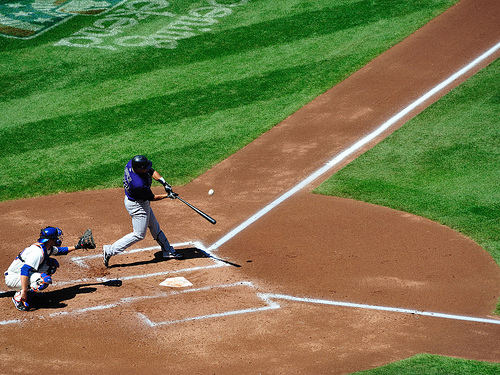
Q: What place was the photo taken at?
A: It was taken at the field.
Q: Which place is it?
A: It is a field.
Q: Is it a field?
A: Yes, it is a field.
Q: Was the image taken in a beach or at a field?
A: It was taken at a field.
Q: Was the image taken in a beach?
A: No, the picture was taken in a field.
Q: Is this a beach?
A: No, it is a field.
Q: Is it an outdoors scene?
A: Yes, it is outdoors.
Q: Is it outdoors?
A: Yes, it is outdoors.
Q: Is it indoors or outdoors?
A: It is outdoors.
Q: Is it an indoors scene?
A: No, it is outdoors.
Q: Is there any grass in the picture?
A: Yes, there is grass.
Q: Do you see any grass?
A: Yes, there is grass.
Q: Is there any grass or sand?
A: Yes, there is grass.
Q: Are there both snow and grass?
A: No, there is grass but no snow.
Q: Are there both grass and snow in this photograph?
A: No, there is grass but no snow.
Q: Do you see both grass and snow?
A: No, there is grass but no snow.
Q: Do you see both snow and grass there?
A: No, there is grass but no snow.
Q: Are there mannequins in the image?
A: No, there are no mannequins.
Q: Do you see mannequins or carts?
A: No, there are no mannequins or carts.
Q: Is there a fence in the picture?
A: No, there are no fences.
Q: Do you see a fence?
A: No, there are no fences.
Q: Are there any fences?
A: No, there are no fences.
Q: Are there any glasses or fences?
A: No, there are no fences or glasses.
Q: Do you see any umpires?
A: No, there are no umpires.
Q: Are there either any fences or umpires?
A: No, there are no umpires or fences.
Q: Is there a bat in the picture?
A: Yes, there is a bat.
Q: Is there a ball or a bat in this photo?
A: Yes, there is a bat.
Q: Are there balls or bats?
A: Yes, there is a bat.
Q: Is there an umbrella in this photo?
A: No, there are no umbrellas.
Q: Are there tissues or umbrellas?
A: No, there are no umbrellas or tissues.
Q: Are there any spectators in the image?
A: No, there are no spectators.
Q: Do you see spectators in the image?
A: No, there are no spectators.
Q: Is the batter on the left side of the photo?
A: Yes, the batter is on the left of the image.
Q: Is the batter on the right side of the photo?
A: No, the batter is on the left of the image.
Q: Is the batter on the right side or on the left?
A: The batter is on the left of the image.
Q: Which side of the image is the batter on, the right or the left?
A: The batter is on the left of the image.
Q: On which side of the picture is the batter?
A: The batter is on the left of the image.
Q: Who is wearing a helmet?
A: The batter is wearing a helmet.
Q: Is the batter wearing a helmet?
A: Yes, the batter is wearing a helmet.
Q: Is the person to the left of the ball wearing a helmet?
A: Yes, the batter is wearing a helmet.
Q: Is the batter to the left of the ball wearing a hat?
A: No, the batter is wearing a helmet.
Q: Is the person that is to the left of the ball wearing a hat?
A: No, the batter is wearing a helmet.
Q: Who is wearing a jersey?
A: The batter is wearing a jersey.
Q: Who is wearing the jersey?
A: The batter is wearing a jersey.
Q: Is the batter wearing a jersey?
A: Yes, the batter is wearing a jersey.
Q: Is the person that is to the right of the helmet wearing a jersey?
A: Yes, the batter is wearing a jersey.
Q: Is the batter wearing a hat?
A: No, the batter is wearing a jersey.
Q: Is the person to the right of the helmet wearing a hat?
A: No, the batter is wearing a jersey.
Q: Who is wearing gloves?
A: The batter is wearing gloves.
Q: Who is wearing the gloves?
A: The batter is wearing gloves.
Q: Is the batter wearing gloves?
A: Yes, the batter is wearing gloves.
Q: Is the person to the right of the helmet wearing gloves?
A: Yes, the batter is wearing gloves.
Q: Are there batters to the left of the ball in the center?
A: Yes, there is a batter to the left of the ball.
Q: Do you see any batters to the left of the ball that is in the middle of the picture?
A: Yes, there is a batter to the left of the ball.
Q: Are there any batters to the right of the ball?
A: No, the batter is to the left of the ball.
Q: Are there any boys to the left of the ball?
A: No, there is a batter to the left of the ball.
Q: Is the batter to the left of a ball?
A: Yes, the batter is to the left of a ball.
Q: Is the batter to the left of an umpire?
A: No, the batter is to the left of a ball.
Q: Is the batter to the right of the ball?
A: No, the batter is to the left of the ball.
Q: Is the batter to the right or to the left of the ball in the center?
A: The batter is to the left of the ball.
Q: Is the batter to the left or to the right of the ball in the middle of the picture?
A: The batter is to the left of the ball.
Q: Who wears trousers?
A: The batter wears trousers.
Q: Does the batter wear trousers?
A: Yes, the batter wears trousers.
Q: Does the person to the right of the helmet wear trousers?
A: Yes, the batter wears trousers.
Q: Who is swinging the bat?
A: The batter is swinging the bat.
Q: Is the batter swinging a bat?
A: Yes, the batter is swinging a bat.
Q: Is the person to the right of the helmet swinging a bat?
A: Yes, the batter is swinging a bat.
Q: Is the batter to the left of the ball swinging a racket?
A: No, the batter is swinging a bat.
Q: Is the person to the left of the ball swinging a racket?
A: No, the batter is swinging a bat.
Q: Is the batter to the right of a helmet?
A: Yes, the batter is to the right of a helmet.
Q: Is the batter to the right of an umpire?
A: No, the batter is to the right of a helmet.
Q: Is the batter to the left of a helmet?
A: No, the batter is to the right of a helmet.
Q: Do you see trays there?
A: No, there are no trays.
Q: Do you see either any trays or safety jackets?
A: No, there are no trays or safety jackets.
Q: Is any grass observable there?
A: Yes, there is grass.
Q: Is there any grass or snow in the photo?
A: Yes, there is grass.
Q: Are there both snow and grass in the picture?
A: No, there is grass but no snow.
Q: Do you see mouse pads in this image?
A: No, there are no mouse pads.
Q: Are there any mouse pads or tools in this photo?
A: No, there are no mouse pads or tools.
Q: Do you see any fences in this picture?
A: No, there are no fences.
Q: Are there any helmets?
A: Yes, there is a helmet.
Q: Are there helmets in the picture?
A: Yes, there is a helmet.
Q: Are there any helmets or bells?
A: Yes, there is a helmet.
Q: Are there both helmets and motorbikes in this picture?
A: No, there is a helmet but no motorcycles.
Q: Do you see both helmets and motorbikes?
A: No, there is a helmet but no motorcycles.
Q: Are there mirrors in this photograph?
A: No, there are no mirrors.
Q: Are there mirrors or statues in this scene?
A: No, there are no mirrors or statues.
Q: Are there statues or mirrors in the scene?
A: No, there are no mirrors or statues.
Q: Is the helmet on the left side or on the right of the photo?
A: The helmet is on the left of the image.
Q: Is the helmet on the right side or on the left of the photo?
A: The helmet is on the left of the image.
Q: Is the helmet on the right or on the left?
A: The helmet is on the left of the image.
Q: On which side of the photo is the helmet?
A: The helmet is on the left of the image.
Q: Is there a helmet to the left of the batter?
A: Yes, there is a helmet to the left of the batter.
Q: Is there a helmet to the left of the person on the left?
A: Yes, there is a helmet to the left of the batter.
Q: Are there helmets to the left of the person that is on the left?
A: Yes, there is a helmet to the left of the batter.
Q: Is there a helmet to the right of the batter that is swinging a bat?
A: No, the helmet is to the left of the batter.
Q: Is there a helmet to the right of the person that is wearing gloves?
A: No, the helmet is to the left of the batter.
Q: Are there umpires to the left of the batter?
A: No, there is a helmet to the left of the batter.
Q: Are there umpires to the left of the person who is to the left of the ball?
A: No, there is a helmet to the left of the batter.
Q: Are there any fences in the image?
A: No, there are no fences.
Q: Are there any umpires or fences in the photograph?
A: No, there are no fences or umpires.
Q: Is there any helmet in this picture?
A: Yes, there is a helmet.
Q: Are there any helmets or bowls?
A: Yes, there is a helmet.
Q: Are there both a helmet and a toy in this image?
A: No, there is a helmet but no toys.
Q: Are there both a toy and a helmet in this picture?
A: No, there is a helmet but no toys.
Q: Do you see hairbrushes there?
A: No, there are no hairbrushes.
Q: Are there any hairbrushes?
A: No, there are no hairbrushes.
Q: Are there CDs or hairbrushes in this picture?
A: No, there are no hairbrushes or cds.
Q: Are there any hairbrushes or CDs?
A: No, there are no hairbrushes or cds.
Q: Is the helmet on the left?
A: Yes, the helmet is on the left of the image.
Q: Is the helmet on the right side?
A: No, the helmet is on the left of the image.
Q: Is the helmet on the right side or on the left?
A: The helmet is on the left of the image.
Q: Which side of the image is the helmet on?
A: The helmet is on the left of the image.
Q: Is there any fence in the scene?
A: No, there are no fences.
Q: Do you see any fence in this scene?
A: No, there are no fences.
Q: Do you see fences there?
A: No, there are no fences.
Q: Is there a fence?
A: No, there are no fences.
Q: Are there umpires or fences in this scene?
A: No, there are no fences or umpires.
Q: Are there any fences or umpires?
A: No, there are no fences or umpires.